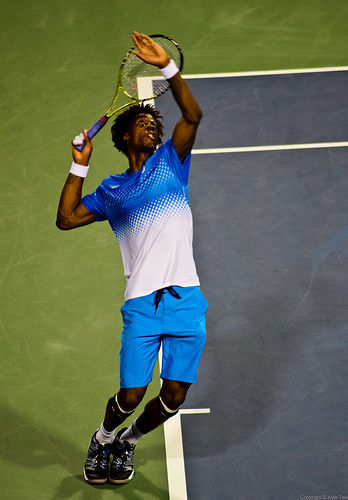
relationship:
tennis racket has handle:
[73, 34, 183, 151] [70, 115, 109, 151]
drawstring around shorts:
[150, 285, 182, 312] [118, 285, 210, 388]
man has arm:
[54, 29, 209, 486] [159, 54, 203, 164]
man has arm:
[54, 29, 209, 486] [53, 171, 104, 230]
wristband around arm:
[155, 58, 180, 82] [159, 54, 203, 164]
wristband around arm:
[67, 159, 91, 179] [53, 171, 104, 230]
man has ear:
[54, 29, 209, 486] [122, 129, 130, 143]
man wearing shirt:
[54, 29, 209, 486] [81, 138, 199, 301]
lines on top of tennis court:
[134, 66, 347, 499] [1, 1, 346, 499]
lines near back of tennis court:
[135, 66, 346, 155] [1, 1, 346, 499]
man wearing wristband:
[54, 29, 209, 486] [155, 58, 180, 82]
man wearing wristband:
[54, 29, 209, 486] [67, 159, 91, 179]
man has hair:
[54, 29, 209, 486] [108, 99, 163, 150]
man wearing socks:
[54, 29, 209, 486] [94, 419, 146, 447]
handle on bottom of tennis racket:
[70, 115, 109, 151] [73, 34, 183, 151]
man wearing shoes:
[54, 29, 209, 486] [84, 424, 136, 485]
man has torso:
[54, 29, 209, 486] [99, 146, 201, 293]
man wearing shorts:
[54, 29, 209, 486] [118, 285, 210, 388]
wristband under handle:
[67, 159, 91, 179] [71, 128, 94, 166]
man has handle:
[54, 29, 209, 486] [71, 128, 94, 166]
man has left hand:
[54, 29, 209, 486] [128, 29, 166, 66]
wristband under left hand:
[155, 58, 180, 82] [128, 29, 166, 66]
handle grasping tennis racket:
[71, 128, 94, 166] [73, 34, 183, 151]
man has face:
[54, 29, 209, 486] [134, 110, 159, 152]